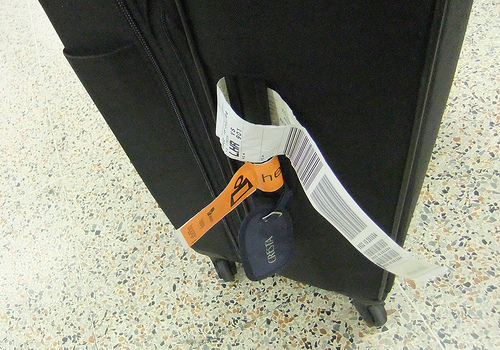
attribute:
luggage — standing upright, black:
[37, 0, 474, 329]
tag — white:
[222, 63, 391, 245]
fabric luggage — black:
[39, 3, 461, 324]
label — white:
[209, 74, 448, 291]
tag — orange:
[119, 144, 298, 248]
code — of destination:
[214, 134, 239, 155]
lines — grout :
[2, 0, 102, 348]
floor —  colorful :
[45, 254, 190, 331]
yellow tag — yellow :
[157, 157, 280, 249]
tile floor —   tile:
[1, 1, 498, 348]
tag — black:
[245, 205, 297, 304]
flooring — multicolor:
[7, 176, 144, 348]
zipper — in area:
[167, 5, 238, 266]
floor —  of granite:
[3, 0, 177, 348]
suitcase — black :
[36, 0, 478, 326]